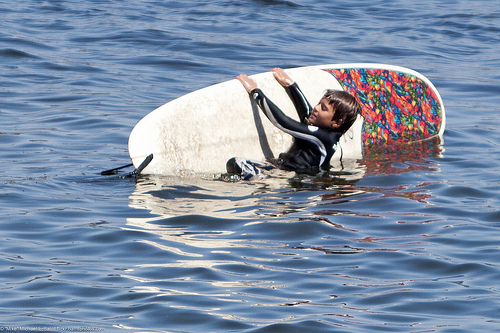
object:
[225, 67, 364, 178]
kid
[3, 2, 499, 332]
water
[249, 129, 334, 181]
wetsuit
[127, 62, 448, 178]
surfboard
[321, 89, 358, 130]
hair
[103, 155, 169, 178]
fins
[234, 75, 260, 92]
left hand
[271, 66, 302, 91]
right hand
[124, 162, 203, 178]
cord